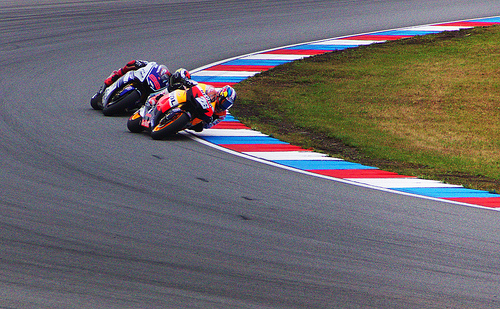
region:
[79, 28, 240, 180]
two bikers on the street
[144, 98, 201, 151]
front tire of bike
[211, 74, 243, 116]
helmet of the biker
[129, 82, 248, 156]
biker with many colors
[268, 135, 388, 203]
red white and blue street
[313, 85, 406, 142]
grass next to road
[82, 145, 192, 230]
street under the bikers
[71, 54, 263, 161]
two bikers turning bikes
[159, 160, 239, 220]
mark on the street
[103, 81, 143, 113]
front tire of blue bike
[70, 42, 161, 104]
Person riding a motorcycke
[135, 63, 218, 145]
Person riding a motorcycke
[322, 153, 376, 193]
Red and blue stripe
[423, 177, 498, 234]
Red and blue stripe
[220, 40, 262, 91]
Red and blue stripe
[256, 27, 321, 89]
Red and blue stripe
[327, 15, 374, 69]
Red and blue stripe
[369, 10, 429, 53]
Red and blue stripe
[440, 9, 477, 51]
Red and blue stripe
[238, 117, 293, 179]
Red and blue stripe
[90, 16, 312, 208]
two bikes in the road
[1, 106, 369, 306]
a clean neat road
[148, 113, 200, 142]
wheel of the bike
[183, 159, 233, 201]
a small mark on road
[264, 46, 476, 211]
a beautiful clean grass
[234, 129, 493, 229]
a mutlple colors in road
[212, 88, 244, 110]
helmet of the person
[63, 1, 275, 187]
two players riding bike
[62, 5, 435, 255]
a large curve of road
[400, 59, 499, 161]
an empty sand in road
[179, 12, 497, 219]
red, white and blue stripes on side of track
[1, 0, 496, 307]
black pavement on race track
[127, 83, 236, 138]
rider on yellow and red motorcycle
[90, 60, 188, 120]
rider on blue and white motorcycle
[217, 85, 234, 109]
multi color helmet on head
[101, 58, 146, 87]
red pant leg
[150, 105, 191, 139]
tire with yellow and red wheel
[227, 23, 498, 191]
green grass in center of track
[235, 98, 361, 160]
tire tracks in grass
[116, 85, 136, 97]
royal blue fender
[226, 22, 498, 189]
grass next to race track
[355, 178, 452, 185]
white stripe next to race track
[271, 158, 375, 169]
blue stripe next to race track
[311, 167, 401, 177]
red stripe next to race track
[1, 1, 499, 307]
race track is curved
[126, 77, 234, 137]
motorcycle in front of motorcycle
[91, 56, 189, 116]
motorcycle behind motorcycle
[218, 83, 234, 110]
coloful motorcycle helmet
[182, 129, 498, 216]
white line along race track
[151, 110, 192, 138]
black wheel